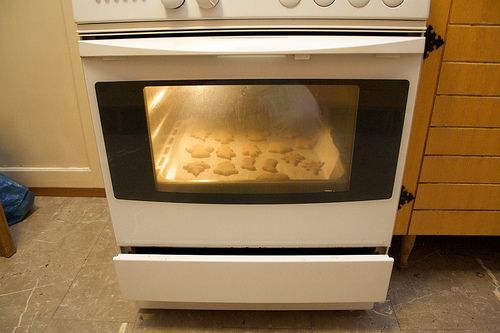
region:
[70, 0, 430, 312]
Cookies baking in white oven.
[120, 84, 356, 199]
cookies cooking in oven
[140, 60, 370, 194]
oven with light on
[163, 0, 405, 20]
white knobs on the stove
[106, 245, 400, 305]
drawer below oven slightly open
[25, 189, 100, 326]
square tile flooring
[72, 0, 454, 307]
photograph of cookies cooking in oven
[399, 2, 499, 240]
light colored wooded cabinets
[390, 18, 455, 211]
two black decorative hinges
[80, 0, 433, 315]
white and black stove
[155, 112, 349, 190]
cookies on silver tray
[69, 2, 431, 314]
Light colored oven with the light on inside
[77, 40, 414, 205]
Window in the door of an oven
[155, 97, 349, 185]
A tray of cookies baking inside an oven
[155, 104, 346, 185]
Sugar cookies on wax paper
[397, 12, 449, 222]
Two black hinges on a cabinet door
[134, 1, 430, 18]
Knobs on the front of a stove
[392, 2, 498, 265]
Wood cabinets in a kitchen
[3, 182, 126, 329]
Linoleum floor in a kitchen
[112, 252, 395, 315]
Drawer on the bottom of an oven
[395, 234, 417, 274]
Small wood leg holding up an cabinet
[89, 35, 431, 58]
white handle on stove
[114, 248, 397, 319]
a storage drawer under the oven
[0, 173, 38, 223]
a blue bag on the floor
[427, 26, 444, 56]
a black hinge on the cabinet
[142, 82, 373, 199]
a glass oven window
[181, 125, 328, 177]
sugar cookies baking in an oven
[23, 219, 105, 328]
gray tile on the floor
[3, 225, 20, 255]
a wooden chair leg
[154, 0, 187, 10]
a white control on the stove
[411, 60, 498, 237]
small cabinet drawers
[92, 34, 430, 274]
white oven in kitchen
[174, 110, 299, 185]
cookies baking in oven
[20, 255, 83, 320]
marble floor under oven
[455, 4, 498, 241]
wood cabinets on right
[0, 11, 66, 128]
white cabinet on left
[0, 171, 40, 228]
blue fabric on ground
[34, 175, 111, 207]
brown wood on bottom of cabinet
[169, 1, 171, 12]
white knob on oven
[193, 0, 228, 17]
white knob on oven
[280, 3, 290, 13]
white knob on oven